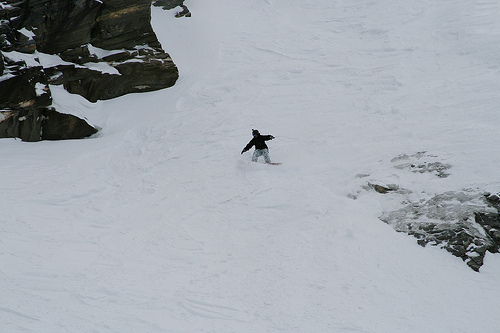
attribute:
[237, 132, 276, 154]
arms — open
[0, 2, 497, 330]
mountain — mountain part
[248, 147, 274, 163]
pants — white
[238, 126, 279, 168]
man — over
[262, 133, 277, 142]
arm — over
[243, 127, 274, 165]
person — snowboarding 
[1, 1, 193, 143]
rocks — big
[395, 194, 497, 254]
rocks — more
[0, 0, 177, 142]
rocks — more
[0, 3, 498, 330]
snow — undisturbed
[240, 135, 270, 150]
jacket — black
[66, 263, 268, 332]
snow — white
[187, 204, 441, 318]
ground — covered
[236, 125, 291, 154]
jacket — black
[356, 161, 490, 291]
rock — gray